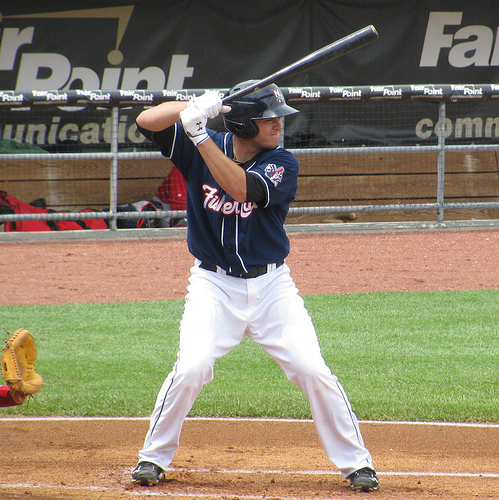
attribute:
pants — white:
[136, 253, 376, 477]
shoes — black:
[350, 468, 379, 489]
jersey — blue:
[165, 124, 299, 266]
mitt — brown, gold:
[3, 329, 44, 398]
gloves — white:
[180, 110, 210, 146]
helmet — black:
[222, 79, 299, 140]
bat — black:
[218, 22, 379, 112]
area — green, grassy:
[0, 289, 498, 424]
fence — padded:
[2, 82, 497, 238]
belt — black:
[196, 260, 286, 282]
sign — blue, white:
[1, 1, 498, 145]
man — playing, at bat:
[134, 24, 381, 495]